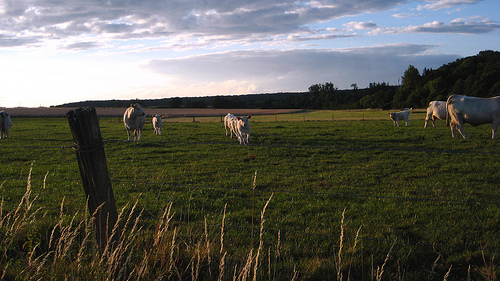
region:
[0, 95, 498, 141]
cows in a green field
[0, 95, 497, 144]
white cows in a field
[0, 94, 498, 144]
seven cows grazing in a field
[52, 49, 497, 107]
green trees in the distance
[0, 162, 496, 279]
tall grass in the front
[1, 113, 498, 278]
low cut grass in the field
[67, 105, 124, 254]
single wooden post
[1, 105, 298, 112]
dirt mound in the distance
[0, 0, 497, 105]
sky with dark clouds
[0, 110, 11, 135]
part of lone cow on the left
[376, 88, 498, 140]
Cows in a pasture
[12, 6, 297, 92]
Clouds in the sky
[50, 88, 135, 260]
A hedgepost for a fence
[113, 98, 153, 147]
A white cow in a green pasture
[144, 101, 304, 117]
This field has been plowed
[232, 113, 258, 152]
A calf running towards the camera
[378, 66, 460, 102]
Trees in the distance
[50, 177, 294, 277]
Tall yellow weeds near a hedge post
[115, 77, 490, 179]
Many cow in a pasture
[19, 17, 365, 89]
It is either dusk or dawn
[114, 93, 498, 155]
White cattle in the field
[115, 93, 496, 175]
A herd of cattlle walking in the grass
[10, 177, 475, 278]
hay in the foreground of the grass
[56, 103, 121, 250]
The wooden post tilted over slightly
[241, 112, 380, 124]
The fence in the field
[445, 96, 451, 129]
The tail of the cattle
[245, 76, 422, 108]
The trees behind the field of grass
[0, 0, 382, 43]
Clouds in the sky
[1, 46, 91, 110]
The glare of the sun in the sky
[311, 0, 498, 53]
The blue sky behind the cloud cover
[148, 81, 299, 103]
mountain on horizon line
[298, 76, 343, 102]
tree on horizon line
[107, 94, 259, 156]
cows in a field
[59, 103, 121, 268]
fence post with tall grass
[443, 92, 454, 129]
tail of a cow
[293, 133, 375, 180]
green foliage in a field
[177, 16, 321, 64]
clouds and blue sky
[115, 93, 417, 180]
animals in a green field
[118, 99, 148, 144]
white cow with head turned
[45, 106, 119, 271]
brown plants next to fence post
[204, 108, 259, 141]
sheep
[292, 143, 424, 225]
the green grass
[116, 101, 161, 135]
a white sheep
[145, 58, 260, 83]
a white cloud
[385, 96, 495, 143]
animals in the field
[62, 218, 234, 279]
hay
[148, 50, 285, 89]
clouds in the sky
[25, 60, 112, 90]
bright light in the sky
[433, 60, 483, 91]
the green bush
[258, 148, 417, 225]
green grass is short